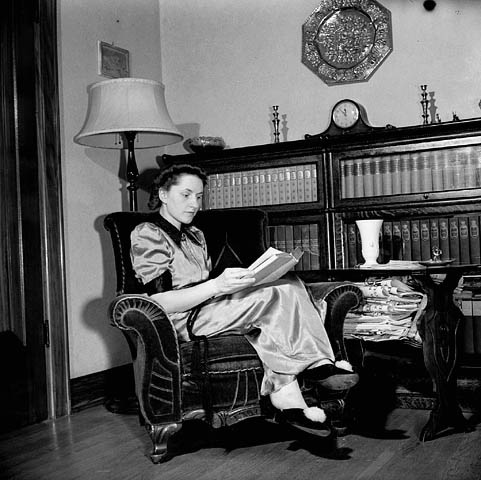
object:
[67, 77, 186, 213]
lamp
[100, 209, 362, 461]
chair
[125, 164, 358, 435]
woman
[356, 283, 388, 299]
paper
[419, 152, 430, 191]
book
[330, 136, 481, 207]
shelf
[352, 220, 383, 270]
vase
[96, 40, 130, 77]
picture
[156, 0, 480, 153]
wall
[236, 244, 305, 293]
book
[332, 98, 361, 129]
clock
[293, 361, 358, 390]
shoes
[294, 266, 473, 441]
desk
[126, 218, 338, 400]
dress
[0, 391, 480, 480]
floor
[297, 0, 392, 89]
plate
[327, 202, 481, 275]
bookshelf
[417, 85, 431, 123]
candle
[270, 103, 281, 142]
cadlestick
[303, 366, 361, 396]
slippers